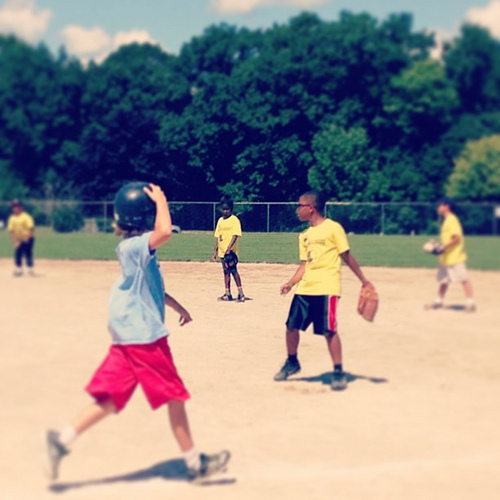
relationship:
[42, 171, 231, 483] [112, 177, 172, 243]
boy wearing helmet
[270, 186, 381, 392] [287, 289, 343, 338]
boy wearing shorts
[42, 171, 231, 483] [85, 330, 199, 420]
boy wearing shorts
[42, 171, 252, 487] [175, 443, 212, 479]
boy wearing socks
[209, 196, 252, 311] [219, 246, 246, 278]
boy wearing shorts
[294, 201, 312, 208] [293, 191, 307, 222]
eyeglasses worn on face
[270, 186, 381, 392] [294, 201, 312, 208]
boy wearing eyeglasses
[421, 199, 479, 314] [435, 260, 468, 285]
boy wearing shorts